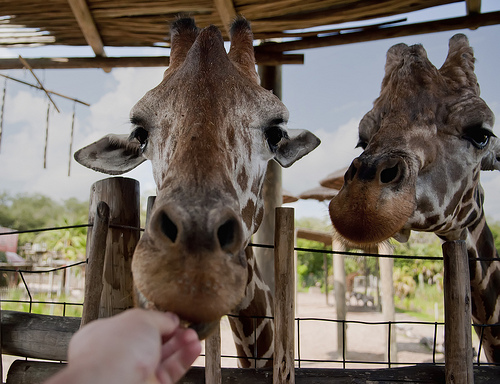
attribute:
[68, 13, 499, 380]
giraffes — they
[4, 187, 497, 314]
trees — long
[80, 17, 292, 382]
giraffe — tall , staring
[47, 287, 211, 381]
hand — human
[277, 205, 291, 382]
pole — wooden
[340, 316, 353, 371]
wire — metal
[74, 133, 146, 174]
ear — little, furry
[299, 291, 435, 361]
pathway — dirt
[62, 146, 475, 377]
posts — wooden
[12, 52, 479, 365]
area — giraffe